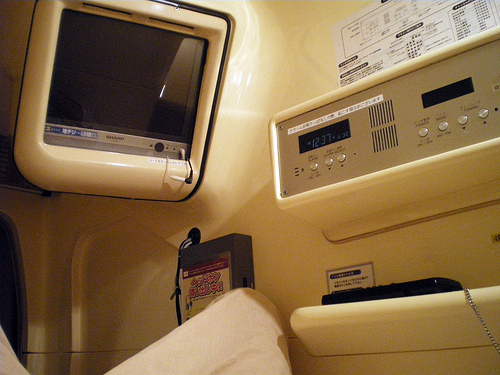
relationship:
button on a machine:
[308, 160, 318, 170] [277, 35, 498, 199]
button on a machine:
[323, 158, 332, 167] [277, 35, 498, 199]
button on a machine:
[335, 153, 347, 161] [277, 35, 498, 199]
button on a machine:
[415, 126, 431, 139] [277, 35, 498, 199]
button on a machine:
[435, 122, 449, 130] [277, 35, 498, 199]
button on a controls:
[478, 106, 490, 121] [264, 23, 499, 238]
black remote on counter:
[314, 274, 462, 303] [291, 285, 498, 355]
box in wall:
[178, 233, 254, 328] [26, 203, 179, 328]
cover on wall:
[325, 262, 375, 294] [2, 17, 497, 372]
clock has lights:
[297, 119, 351, 155] [309, 127, 336, 147]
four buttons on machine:
[416, 105, 492, 138] [254, 16, 498, 243]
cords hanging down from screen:
[164, 145, 196, 193] [45, 7, 208, 141]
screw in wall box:
[272, 122, 278, 130] [262, 33, 497, 253]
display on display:
[43, 6, 211, 161] [43, 6, 211, 161]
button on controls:
[337, 153, 343, 159] [264, 23, 499, 238]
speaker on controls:
[367, 101, 407, 155] [264, 23, 499, 238]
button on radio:
[408, 125, 444, 144] [264, 111, 492, 231]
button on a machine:
[323, 158, 332, 167] [254, 16, 498, 243]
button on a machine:
[337, 153, 343, 159] [261, 47, 499, 373]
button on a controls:
[418, 125, 429, 137] [264, 23, 499, 238]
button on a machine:
[418, 125, 429, 137] [254, 16, 498, 243]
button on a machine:
[456, 104, 468, 129] [254, 16, 498, 243]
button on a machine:
[478, 106, 490, 121] [262, 69, 499, 244]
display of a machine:
[43, 6, 211, 161] [0, 10, 246, 225]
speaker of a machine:
[357, 101, 407, 155] [316, 35, 471, 218]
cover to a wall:
[325, 262, 375, 294] [43, 0, 498, 370]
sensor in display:
[151, 142, 166, 153] [42, 4, 210, 161]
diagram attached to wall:
[336, 0, 498, 89] [246, 4, 358, 113]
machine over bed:
[6, 0, 240, 205] [8, 247, 442, 368]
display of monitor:
[43, 6, 211, 161] [3, 2, 235, 205]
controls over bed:
[264, 23, 499, 238] [4, 278, 293, 373]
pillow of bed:
[165, 313, 250, 356] [0, 222, 479, 372]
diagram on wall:
[336, 2, 498, 60] [283, 0, 497, 372]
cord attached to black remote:
[456, 280, 484, 320] [320, 277, 463, 305]